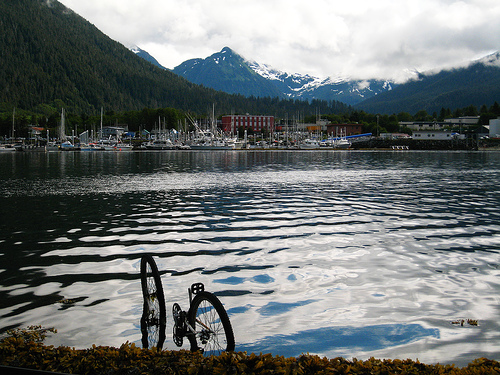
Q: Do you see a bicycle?
A: Yes, there is a bicycle.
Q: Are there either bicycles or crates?
A: Yes, there is a bicycle.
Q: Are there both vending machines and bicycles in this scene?
A: No, there is a bicycle but no vending machines.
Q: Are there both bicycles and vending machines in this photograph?
A: No, there is a bicycle but no vending machines.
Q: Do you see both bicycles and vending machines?
A: No, there is a bicycle but no vending machines.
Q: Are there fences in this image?
A: No, there are no fences.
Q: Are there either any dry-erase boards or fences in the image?
A: No, there are no fences or dry-erase boards.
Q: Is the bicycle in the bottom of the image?
A: Yes, the bicycle is in the bottom of the image.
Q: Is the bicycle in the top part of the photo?
A: No, the bicycle is in the bottom of the image.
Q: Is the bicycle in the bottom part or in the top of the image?
A: The bicycle is in the bottom of the image.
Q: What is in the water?
A: The bicycle is in the water.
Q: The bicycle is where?
A: The bicycle is in the water.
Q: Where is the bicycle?
A: The bicycle is in the water.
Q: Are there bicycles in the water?
A: Yes, there is a bicycle in the water.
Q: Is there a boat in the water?
A: No, there is a bicycle in the water.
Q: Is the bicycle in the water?
A: Yes, the bicycle is in the water.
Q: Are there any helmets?
A: No, there are no helmets.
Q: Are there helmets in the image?
A: No, there are no helmets.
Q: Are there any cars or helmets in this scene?
A: No, there are no helmets or cars.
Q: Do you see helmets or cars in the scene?
A: No, there are no helmets or cars.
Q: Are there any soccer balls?
A: No, there are no soccer balls.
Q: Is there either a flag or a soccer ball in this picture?
A: No, there are no soccer balls or flags.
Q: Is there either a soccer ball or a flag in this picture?
A: No, there are no soccer balls or flags.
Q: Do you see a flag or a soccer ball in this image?
A: No, there are no soccer balls or flags.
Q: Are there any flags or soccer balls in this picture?
A: No, there are no soccer balls or flags.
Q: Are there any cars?
A: No, there are no cars.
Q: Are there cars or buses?
A: No, there are no cars or buses.